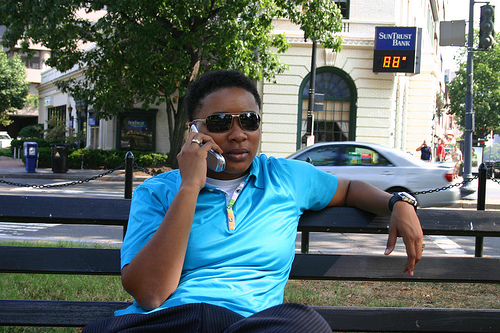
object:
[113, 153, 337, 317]
shirt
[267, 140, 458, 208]
car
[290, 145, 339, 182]
door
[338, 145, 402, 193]
door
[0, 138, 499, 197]
sidewalk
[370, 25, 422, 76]
sign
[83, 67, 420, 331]
man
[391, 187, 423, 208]
wristwatch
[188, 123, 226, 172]
phone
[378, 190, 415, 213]
wrist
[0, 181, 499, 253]
street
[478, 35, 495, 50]
traffic light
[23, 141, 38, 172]
magazine stand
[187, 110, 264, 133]
sunglasses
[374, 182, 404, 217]
wristband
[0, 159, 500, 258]
road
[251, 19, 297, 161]
wall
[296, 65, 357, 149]
window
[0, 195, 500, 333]
bench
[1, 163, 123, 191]
chain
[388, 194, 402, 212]
band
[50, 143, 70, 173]
garbage can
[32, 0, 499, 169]
building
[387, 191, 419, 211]
watch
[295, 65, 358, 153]
frame